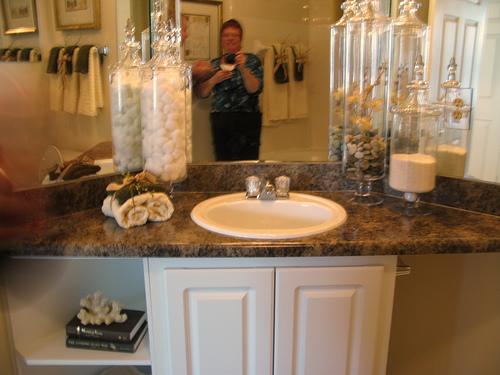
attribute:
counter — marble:
[4, 160, 499, 259]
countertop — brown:
[1, 163, 499, 257]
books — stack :
[60, 293, 143, 353]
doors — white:
[149, 256, 383, 371]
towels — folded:
[92, 158, 178, 224]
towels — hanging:
[38, 46, 118, 127]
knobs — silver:
[236, 174, 269, 201]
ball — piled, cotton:
[131, 60, 200, 165]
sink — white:
[176, 185, 383, 275]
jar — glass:
[138, 20, 188, 181]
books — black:
[66, 304, 146, 354]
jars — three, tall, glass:
[141, 2, 433, 218]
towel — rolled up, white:
[99, 191, 177, 226]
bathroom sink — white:
[192, 189, 347, 238]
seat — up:
[37, 146, 58, 180]